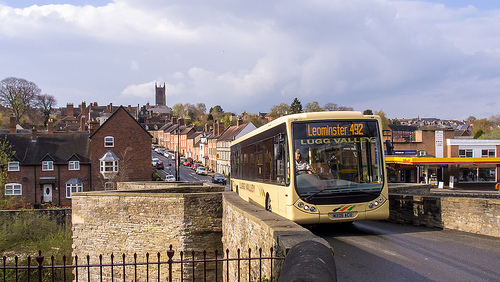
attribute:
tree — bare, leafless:
[1, 76, 42, 124]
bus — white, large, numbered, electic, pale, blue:
[228, 111, 393, 232]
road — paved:
[152, 147, 497, 281]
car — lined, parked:
[196, 167, 211, 178]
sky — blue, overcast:
[0, 1, 499, 122]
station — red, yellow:
[389, 155, 497, 190]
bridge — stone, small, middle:
[68, 179, 314, 278]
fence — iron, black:
[1, 244, 292, 281]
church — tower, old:
[144, 81, 177, 125]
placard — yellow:
[304, 120, 366, 140]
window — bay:
[68, 159, 79, 170]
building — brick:
[0, 103, 153, 211]